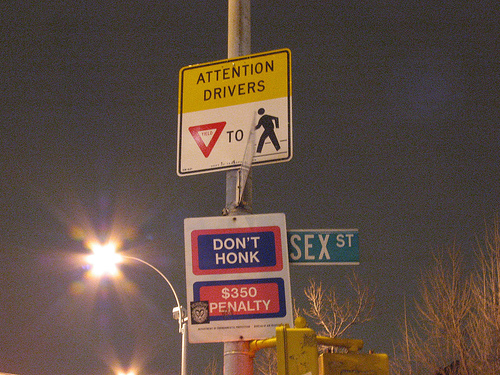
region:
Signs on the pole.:
[153, 15, 376, 360]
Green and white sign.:
[265, 196, 395, 283]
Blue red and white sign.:
[148, 202, 374, 367]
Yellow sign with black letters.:
[173, 22, 343, 189]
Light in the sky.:
[72, 200, 163, 293]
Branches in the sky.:
[265, 233, 433, 354]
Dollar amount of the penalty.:
[206, 264, 376, 349]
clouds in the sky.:
[322, 94, 494, 268]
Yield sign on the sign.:
[174, 116, 237, 162]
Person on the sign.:
[226, 92, 327, 184]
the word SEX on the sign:
[288, 232, 329, 260]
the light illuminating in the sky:
[15, 165, 177, 373]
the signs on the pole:
[175, 45, 360, 343]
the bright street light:
[70, 235, 190, 374]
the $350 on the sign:
[219, 285, 258, 298]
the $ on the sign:
[220, 285, 231, 299]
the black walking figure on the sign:
[251, 106, 282, 153]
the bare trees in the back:
[183, 214, 499, 373]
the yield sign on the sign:
[187, 121, 227, 158]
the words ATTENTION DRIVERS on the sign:
[195, 60, 274, 101]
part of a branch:
[445, 297, 473, 326]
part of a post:
[225, 230, 235, 245]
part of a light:
[101, 250, 118, 263]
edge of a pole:
[233, 328, 238, 357]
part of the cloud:
[362, 120, 381, 150]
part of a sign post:
[311, 245, 315, 249]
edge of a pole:
[220, 335, 235, 364]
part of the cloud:
[371, 199, 378, 210]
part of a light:
[108, 255, 125, 271]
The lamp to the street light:
[63, 225, 130, 292]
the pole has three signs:
[138, 11, 358, 371]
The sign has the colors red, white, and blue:
[179, 203, 294, 348]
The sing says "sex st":
[288, 218, 358, 272]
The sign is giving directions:
[173, 41, 298, 181]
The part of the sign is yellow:
[249, 315, 398, 373]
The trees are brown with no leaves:
[403, 254, 498, 371]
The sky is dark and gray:
[310, 24, 483, 186]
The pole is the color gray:
[212, 8, 262, 49]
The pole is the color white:
[131, 259, 193, 374]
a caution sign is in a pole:
[177, 48, 295, 181]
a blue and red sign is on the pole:
[181, 210, 295, 345]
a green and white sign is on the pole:
[288, 224, 363, 267]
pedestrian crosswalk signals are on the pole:
[251, 325, 389, 374]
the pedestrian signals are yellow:
[253, 322, 390, 373]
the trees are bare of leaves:
[211, 246, 498, 373]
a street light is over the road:
[67, 228, 139, 285]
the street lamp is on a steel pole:
[90, 240, 192, 372]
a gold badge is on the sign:
[189, 298, 211, 329]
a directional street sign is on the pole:
[227, 112, 264, 211]